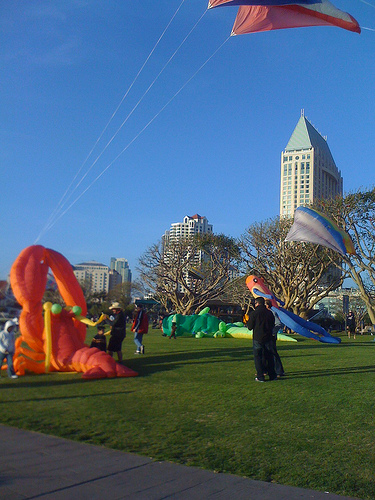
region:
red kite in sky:
[197, 1, 321, 49]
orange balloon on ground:
[10, 260, 78, 390]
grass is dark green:
[184, 387, 284, 468]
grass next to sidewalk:
[181, 385, 289, 459]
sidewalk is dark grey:
[47, 449, 220, 486]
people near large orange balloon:
[95, 226, 181, 368]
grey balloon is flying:
[279, 178, 372, 303]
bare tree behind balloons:
[143, 230, 228, 329]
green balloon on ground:
[160, 307, 286, 346]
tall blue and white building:
[264, 76, 341, 217]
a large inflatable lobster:
[8, 239, 144, 382]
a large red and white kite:
[203, 1, 357, 44]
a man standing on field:
[244, 295, 274, 382]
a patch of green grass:
[0, 308, 370, 489]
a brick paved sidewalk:
[3, 419, 335, 498]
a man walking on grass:
[130, 299, 149, 353]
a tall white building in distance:
[157, 210, 216, 293]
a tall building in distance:
[274, 106, 343, 277]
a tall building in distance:
[71, 252, 130, 299]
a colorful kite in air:
[282, 205, 353, 264]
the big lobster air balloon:
[12, 244, 137, 384]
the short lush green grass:
[90, 382, 315, 455]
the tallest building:
[274, 102, 348, 324]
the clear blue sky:
[176, 105, 257, 204]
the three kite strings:
[30, 13, 241, 228]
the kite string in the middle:
[160, 33, 190, 79]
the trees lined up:
[137, 196, 372, 317]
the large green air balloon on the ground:
[159, 298, 296, 343]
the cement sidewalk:
[17, 433, 169, 497]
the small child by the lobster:
[91, 326, 109, 352]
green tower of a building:
[284, 106, 330, 164]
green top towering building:
[269, 105, 356, 301]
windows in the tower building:
[286, 159, 342, 204]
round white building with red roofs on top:
[157, 210, 211, 327]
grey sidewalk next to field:
[0, 422, 321, 494]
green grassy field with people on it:
[95, 335, 374, 449]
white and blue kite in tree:
[279, 204, 371, 268]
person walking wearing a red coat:
[127, 299, 157, 356]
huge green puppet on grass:
[162, 288, 283, 354]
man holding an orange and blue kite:
[239, 265, 333, 381]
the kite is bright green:
[161, 308, 226, 348]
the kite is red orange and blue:
[242, 270, 295, 319]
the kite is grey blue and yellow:
[285, 203, 362, 277]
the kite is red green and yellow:
[10, 224, 128, 389]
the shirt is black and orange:
[89, 332, 113, 349]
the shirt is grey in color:
[0, 316, 19, 357]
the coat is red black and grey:
[132, 310, 156, 337]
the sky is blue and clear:
[206, 88, 260, 149]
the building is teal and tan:
[277, 102, 331, 218]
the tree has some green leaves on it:
[163, 229, 245, 270]